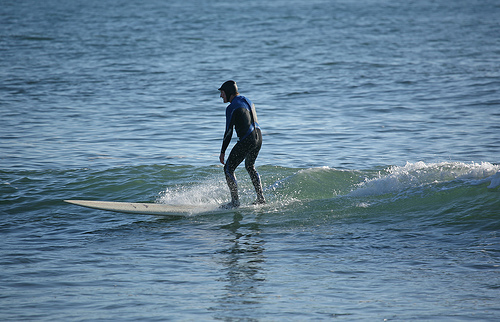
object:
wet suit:
[217, 79, 268, 210]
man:
[215, 78, 267, 209]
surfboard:
[62, 198, 268, 218]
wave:
[343, 156, 499, 219]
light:
[194, 216, 306, 262]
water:
[3, 1, 499, 320]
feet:
[218, 199, 241, 210]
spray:
[149, 163, 303, 223]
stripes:
[239, 121, 262, 142]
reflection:
[206, 207, 267, 308]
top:
[390, 157, 497, 188]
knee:
[223, 163, 233, 176]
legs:
[244, 152, 266, 205]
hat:
[216, 80, 238, 103]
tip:
[61, 199, 76, 205]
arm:
[219, 108, 234, 166]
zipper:
[242, 97, 258, 139]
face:
[219, 91, 228, 103]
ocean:
[3, 2, 500, 322]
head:
[215, 77, 240, 106]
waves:
[265, 163, 383, 201]